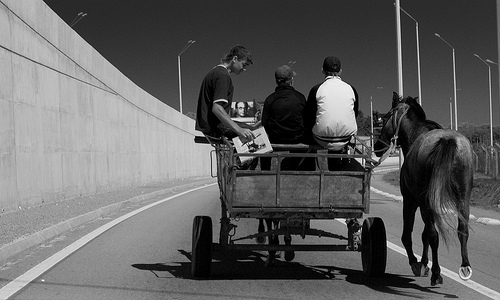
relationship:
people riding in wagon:
[194, 44, 361, 143] [186, 141, 392, 279]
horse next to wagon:
[371, 90, 484, 290] [186, 141, 392, 279]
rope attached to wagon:
[373, 147, 396, 166] [186, 141, 392, 279]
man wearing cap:
[264, 65, 306, 135] [276, 61, 298, 80]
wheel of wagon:
[187, 213, 216, 279] [186, 141, 392, 279]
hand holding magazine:
[238, 129, 255, 138] [233, 125, 273, 157]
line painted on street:
[82, 214, 122, 243] [129, 220, 160, 245]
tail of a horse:
[428, 136, 466, 250] [371, 90, 484, 290]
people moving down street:
[194, 44, 361, 143] [129, 220, 160, 245]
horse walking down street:
[371, 90, 484, 290] [129, 220, 160, 245]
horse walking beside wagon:
[371, 90, 484, 290] [186, 141, 392, 279]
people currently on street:
[194, 44, 361, 143] [129, 220, 160, 245]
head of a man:
[272, 59, 299, 90] [264, 65, 306, 135]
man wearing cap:
[302, 53, 365, 145] [323, 52, 343, 74]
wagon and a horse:
[186, 141, 392, 279] [371, 90, 484, 290]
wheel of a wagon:
[187, 213, 216, 279] [186, 141, 392, 279]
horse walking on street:
[371, 90, 484, 290] [129, 220, 160, 245]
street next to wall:
[129, 220, 160, 245] [1, 14, 174, 193]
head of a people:
[220, 40, 254, 78] [194, 44, 258, 142]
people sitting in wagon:
[194, 44, 361, 143] [186, 141, 392, 279]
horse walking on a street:
[371, 90, 484, 290] [129, 220, 160, 245]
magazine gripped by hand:
[233, 125, 273, 157] [238, 129, 255, 138]